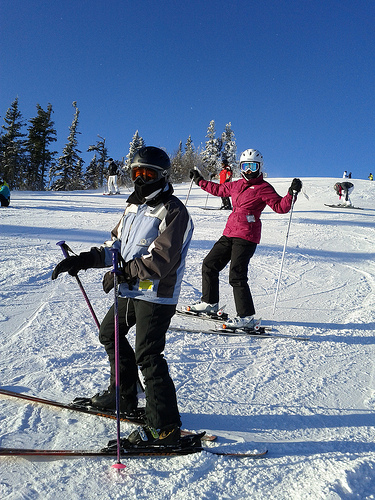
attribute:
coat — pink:
[204, 175, 287, 240]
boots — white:
[199, 262, 274, 335]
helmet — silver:
[237, 147, 264, 180]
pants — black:
[87, 287, 207, 444]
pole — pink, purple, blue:
[93, 237, 140, 481]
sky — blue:
[1, 0, 373, 190]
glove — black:
[49, 246, 105, 280]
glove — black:
[102, 259, 137, 292]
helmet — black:
[128, 142, 183, 191]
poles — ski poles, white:
[184, 158, 299, 283]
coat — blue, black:
[77, 185, 194, 306]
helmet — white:
[234, 143, 262, 179]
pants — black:
[199, 233, 256, 313]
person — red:
[175, 132, 315, 340]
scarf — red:
[332, 180, 346, 201]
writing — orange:
[4, 447, 196, 459]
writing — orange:
[0, 390, 171, 432]